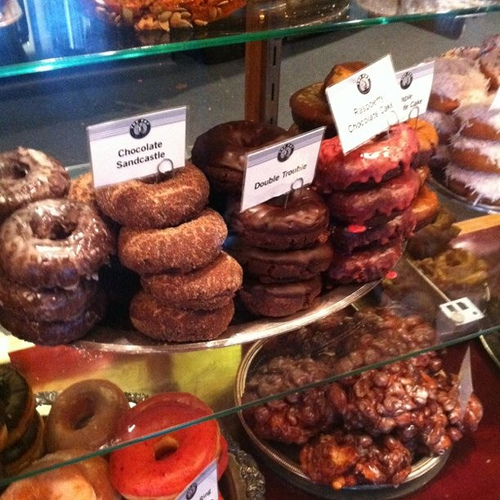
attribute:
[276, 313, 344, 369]
donut — fresh baked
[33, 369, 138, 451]
donut — FRESH , SMALL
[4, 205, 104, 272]
donut — fresh, glazed, delicious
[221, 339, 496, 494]
metal — round, object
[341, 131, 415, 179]
glaze — pink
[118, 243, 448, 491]
container — metal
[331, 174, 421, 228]
red donut — fresh, glazed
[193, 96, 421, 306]
donut stack — sign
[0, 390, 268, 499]
platter — metal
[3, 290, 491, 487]
shelf — brown and metal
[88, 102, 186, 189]
sandcastle sign — chocolate sandcastle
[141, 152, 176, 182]
clip — black and metal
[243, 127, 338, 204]
tag — clip holding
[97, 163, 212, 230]
doughnuts — glazed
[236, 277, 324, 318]
donut — glazed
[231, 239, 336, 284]
donut — glazed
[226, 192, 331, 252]
donut — glazed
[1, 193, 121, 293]
donut — fresh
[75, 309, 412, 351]
plate — metal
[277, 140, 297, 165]
logo — brand, image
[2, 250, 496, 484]
shelf — middle glass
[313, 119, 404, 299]
donuts — glazed, stack